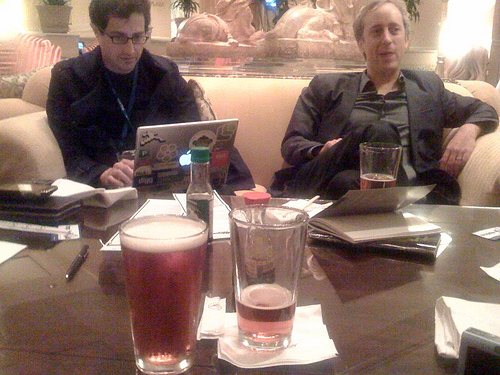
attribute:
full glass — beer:
[115, 210, 212, 373]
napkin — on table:
[219, 309, 338, 370]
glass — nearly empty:
[223, 201, 310, 353]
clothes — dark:
[269, 64, 499, 201]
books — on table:
[311, 187, 441, 268]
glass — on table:
[356, 141, 406, 212]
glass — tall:
[226, 203, 300, 350]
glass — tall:
[111, 210, 206, 373]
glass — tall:
[356, 140, 401, 194]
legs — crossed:
[287, 120, 407, 194]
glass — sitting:
[228, 205, 307, 349]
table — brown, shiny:
[0, 207, 499, 371]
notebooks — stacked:
[306, 182, 443, 250]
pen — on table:
[62, 240, 91, 282]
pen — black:
[56, 247, 97, 283]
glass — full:
[89, 179, 216, 339]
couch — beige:
[3, 60, 497, 202]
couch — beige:
[11, 64, 498, 225]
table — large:
[7, 194, 496, 369]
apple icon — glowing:
[181, 145, 202, 183]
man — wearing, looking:
[49, 0, 203, 125]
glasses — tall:
[92, 200, 309, 374]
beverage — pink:
[124, 243, 201, 358]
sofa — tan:
[0, 76, 499, 206]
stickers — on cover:
[137, 130, 228, 185]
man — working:
[37, 6, 182, 138]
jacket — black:
[267, 67, 497, 201]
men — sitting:
[37, 0, 497, 203]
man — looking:
[273, 1, 498, 210]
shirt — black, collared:
[280, 70, 498, 202]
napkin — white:
[216, 302, 337, 369]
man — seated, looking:
[42, 2, 201, 192]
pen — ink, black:
[55, 239, 97, 284]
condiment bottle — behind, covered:
[186, 145, 213, 242]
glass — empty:
[208, 170, 323, 373]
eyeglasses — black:
[106, 32, 150, 42]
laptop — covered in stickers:
[124, 118, 264, 188]